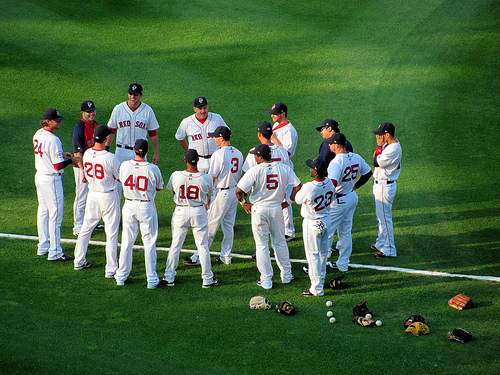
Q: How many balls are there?
A: Five.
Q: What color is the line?
A: White.